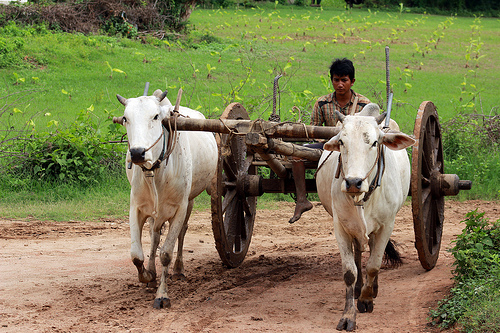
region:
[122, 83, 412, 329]
Cows pulling a cart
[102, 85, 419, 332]
Cows are pulling a cart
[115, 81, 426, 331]
White cows pulling a cart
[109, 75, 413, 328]
White cows are pulling a cart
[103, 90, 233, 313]
Cow pulling a cart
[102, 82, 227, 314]
Cow is pulling a cart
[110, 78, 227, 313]
White cow pulling a cart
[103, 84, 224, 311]
White cow is pulling a cart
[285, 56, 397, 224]
Man sitting on a cart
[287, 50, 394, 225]
Man is sitting on a cart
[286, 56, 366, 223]
the man on the trailer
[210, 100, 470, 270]
the trailer behind the bulls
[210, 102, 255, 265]
the wheel on the trailer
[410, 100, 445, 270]
the wheel on the trailer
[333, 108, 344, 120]
the horn on the bull's head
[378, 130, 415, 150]
the ear on the bull's head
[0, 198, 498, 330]
the trail made of dirt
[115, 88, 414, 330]
the bulls pulling the trailer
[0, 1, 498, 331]
the greenery around the man in the trailer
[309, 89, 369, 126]
the shirt on the man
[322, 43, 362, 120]
man with black hair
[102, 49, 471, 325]
man on wagon with oxen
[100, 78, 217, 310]
animal towing a wagon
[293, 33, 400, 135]
man wearing plaid shirt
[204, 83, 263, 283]
a wooden wagon wheel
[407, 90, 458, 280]
a wooden wagon wheel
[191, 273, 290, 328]
part of a dirt path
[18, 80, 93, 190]
grass and sticks in the background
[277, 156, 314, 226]
man's bare foot on wagon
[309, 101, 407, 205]
white animals head and large ears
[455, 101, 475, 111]
plant growing in field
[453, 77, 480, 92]
plant growing in field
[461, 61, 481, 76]
plant growing in field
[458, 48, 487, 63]
plant growing in field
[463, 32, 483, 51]
plant growing in field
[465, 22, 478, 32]
plant growing in field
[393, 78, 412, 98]
plant growing in field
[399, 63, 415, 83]
plant growing in field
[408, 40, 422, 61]
plant growing in field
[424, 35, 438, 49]
plant growing in field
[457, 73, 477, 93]
green plant growing in field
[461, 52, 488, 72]
green plant growing in field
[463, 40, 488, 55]
green plant growing in field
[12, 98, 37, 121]
green plant growing in field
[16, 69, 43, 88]
green plant growing in field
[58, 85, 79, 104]
green plant growing in field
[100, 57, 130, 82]
green plant growing in field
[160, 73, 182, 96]
green plant growing in field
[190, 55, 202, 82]
green plant growing in field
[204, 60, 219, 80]
green plant growing in field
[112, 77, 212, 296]
An oxen on the left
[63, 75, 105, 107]
Grass in field is green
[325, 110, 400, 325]
An oxen on the right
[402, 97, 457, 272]
Large wooden wheel on right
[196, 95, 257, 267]
Large wooden wheel on left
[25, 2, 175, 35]
Twigs are on hillside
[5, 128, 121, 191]
Small bush on left side of road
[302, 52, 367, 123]
Man sitting in wooden cart